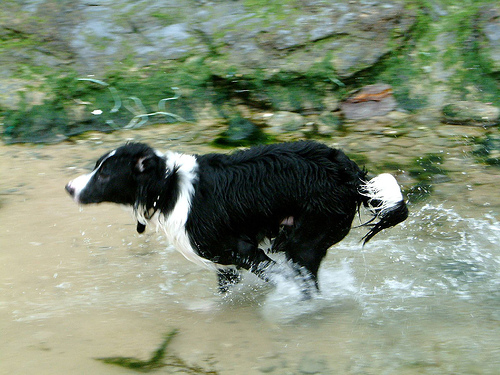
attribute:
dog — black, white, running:
[66, 139, 410, 316]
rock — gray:
[340, 79, 395, 121]